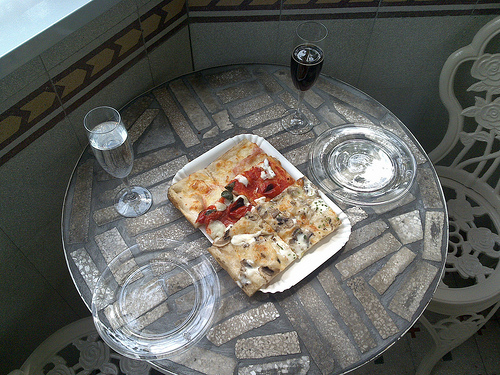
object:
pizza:
[168, 140, 341, 297]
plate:
[172, 134, 351, 294]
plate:
[308, 123, 417, 207]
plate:
[92, 238, 220, 361]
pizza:
[208, 209, 296, 297]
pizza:
[254, 179, 341, 258]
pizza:
[208, 143, 294, 205]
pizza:
[168, 169, 255, 240]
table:
[63, 64, 449, 375]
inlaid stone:
[153, 87, 200, 148]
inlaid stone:
[335, 233, 403, 277]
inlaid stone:
[229, 93, 273, 120]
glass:
[83, 105, 153, 218]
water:
[90, 121, 134, 178]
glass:
[282, 21, 328, 135]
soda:
[291, 45, 323, 92]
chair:
[0, 316, 163, 374]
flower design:
[79, 344, 109, 369]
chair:
[415, 15, 500, 375]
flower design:
[450, 252, 494, 282]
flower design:
[460, 52, 498, 130]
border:
[1, 1, 499, 167]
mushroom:
[232, 232, 264, 247]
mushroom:
[264, 267, 273, 276]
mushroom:
[215, 231, 232, 245]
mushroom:
[242, 260, 252, 268]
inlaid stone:
[234, 332, 300, 357]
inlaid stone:
[389, 260, 439, 321]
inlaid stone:
[294, 282, 361, 369]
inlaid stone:
[317, 267, 379, 355]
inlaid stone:
[388, 209, 423, 245]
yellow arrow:
[55, 69, 87, 97]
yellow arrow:
[117, 28, 141, 56]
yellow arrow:
[22, 92, 59, 123]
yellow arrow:
[87, 46, 115, 78]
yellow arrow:
[142, 11, 161, 37]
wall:
[1, 0, 497, 373]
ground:
[348, 226, 498, 374]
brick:
[408, 328, 485, 374]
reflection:
[319, 127, 408, 194]